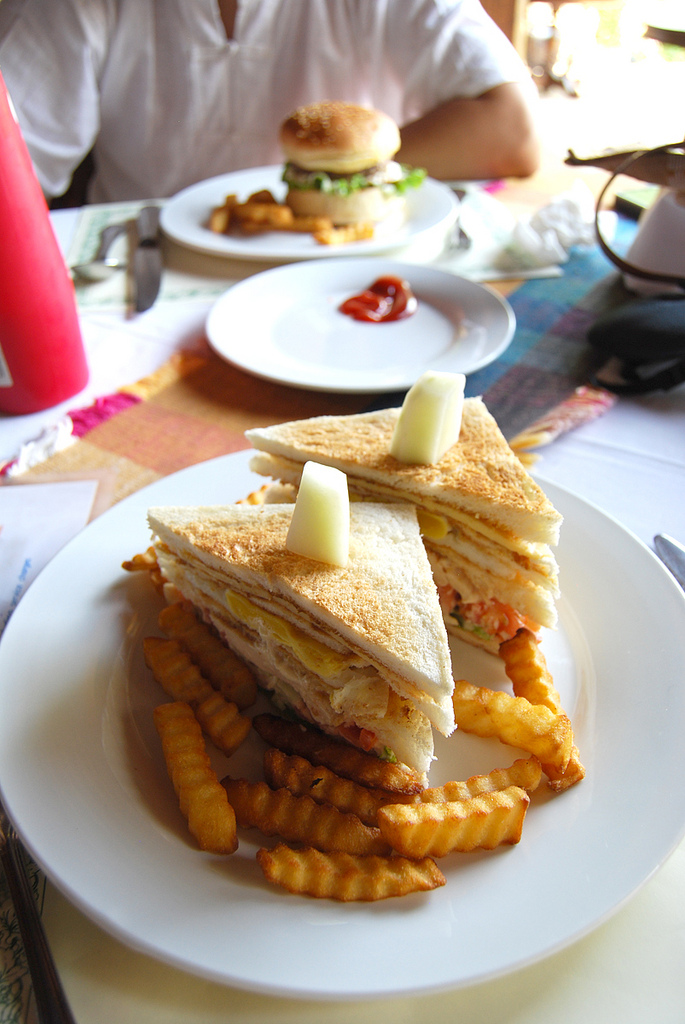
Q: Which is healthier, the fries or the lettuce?
A: The lettuce is healthier than the fries.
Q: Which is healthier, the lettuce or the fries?
A: The lettuce is healthier than the fries.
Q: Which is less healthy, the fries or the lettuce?
A: The fries is less healthy than the lettuce.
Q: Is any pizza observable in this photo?
A: No, there are no pizzas.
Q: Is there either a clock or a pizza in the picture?
A: No, there are no pizzas or clocks.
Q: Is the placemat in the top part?
A: Yes, the placemat is in the top of the image.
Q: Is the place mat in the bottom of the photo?
A: No, the place mat is in the top of the image.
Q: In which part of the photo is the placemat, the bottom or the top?
A: The placemat is in the top of the image.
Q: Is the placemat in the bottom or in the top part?
A: The placemat is in the top of the image.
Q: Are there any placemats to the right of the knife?
A: Yes, there is a placemat to the right of the knife.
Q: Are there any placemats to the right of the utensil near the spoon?
A: Yes, there is a placemat to the right of the knife.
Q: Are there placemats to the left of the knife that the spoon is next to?
A: No, the placemat is to the right of the knife.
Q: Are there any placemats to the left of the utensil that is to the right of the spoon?
A: No, the placemat is to the right of the knife.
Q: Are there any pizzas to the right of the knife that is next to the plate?
A: No, there is a placemat to the right of the knife.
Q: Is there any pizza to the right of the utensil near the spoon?
A: No, there is a placemat to the right of the knife.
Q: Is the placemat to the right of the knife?
A: Yes, the placemat is to the right of the knife.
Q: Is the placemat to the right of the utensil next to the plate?
A: Yes, the placemat is to the right of the knife.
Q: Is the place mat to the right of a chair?
A: No, the place mat is to the right of the knife.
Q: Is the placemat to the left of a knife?
A: No, the placemat is to the right of a knife.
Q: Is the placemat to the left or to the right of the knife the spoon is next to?
A: The placemat is to the right of the knife.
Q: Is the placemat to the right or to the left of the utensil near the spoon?
A: The placemat is to the right of the knife.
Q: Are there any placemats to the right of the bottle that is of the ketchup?
A: Yes, there is a placemat to the right of the bottle.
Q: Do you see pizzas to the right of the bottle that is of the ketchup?
A: No, there is a placemat to the right of the bottle.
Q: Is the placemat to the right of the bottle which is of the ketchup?
A: Yes, the placemat is to the right of the bottle.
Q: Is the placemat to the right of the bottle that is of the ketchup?
A: Yes, the placemat is to the right of the bottle.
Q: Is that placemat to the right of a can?
A: No, the placemat is to the right of the bottle.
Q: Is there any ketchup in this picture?
A: Yes, there is ketchup.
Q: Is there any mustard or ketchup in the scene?
A: Yes, there is ketchup.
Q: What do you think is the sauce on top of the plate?
A: The sauce is ketchup.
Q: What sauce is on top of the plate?
A: The sauce is ketchup.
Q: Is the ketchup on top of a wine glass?
A: No, the ketchup is on top of a plate.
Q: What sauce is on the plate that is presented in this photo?
A: The sauce is ketchup.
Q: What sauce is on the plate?
A: The sauce is ketchup.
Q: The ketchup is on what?
A: The ketchup is on the plate.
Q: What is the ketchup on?
A: The ketchup is on the plate.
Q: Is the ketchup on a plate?
A: Yes, the ketchup is on a plate.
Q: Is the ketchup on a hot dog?
A: No, the ketchup is on a plate.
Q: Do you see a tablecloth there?
A: Yes, there is a tablecloth.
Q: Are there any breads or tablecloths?
A: Yes, there is a tablecloth.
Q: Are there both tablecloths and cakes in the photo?
A: No, there is a tablecloth but no cakes.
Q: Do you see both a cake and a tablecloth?
A: No, there is a tablecloth but no cakes.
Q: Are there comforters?
A: No, there are no comforters.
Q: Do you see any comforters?
A: No, there are no comforters.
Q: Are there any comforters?
A: No, there are no comforters.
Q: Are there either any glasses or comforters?
A: No, there are no comforters or glasses.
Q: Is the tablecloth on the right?
A: Yes, the tablecloth is on the right of the image.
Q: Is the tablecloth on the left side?
A: No, the tablecloth is on the right of the image.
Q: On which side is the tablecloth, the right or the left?
A: The tablecloth is on the right of the image.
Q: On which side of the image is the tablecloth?
A: The tablecloth is on the right of the image.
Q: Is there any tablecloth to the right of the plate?
A: Yes, there is a tablecloth to the right of the plate.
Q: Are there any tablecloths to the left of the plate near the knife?
A: No, the tablecloth is to the right of the plate.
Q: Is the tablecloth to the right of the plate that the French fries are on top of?
A: Yes, the tablecloth is to the right of the plate.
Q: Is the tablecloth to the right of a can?
A: No, the tablecloth is to the right of the plate.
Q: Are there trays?
A: No, there are no trays.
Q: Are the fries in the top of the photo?
A: Yes, the fries are in the top of the image.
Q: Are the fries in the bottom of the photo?
A: No, the fries are in the top of the image.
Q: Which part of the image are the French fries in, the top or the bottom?
A: The French fries are in the top of the image.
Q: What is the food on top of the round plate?
A: The food is fries.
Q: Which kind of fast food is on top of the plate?
A: The food is fries.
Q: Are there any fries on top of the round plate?
A: Yes, there are fries on top of the plate.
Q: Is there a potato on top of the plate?
A: No, there are fries on top of the plate.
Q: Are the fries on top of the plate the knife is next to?
A: Yes, the fries are on top of the plate.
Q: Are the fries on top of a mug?
A: No, the fries are on top of the plate.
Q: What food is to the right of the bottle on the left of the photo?
A: The food is fries.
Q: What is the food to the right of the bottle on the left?
A: The food is fries.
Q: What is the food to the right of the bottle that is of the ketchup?
A: The food is fries.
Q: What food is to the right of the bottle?
A: The food is fries.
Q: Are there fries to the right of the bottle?
A: Yes, there are fries to the right of the bottle.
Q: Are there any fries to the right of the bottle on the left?
A: Yes, there are fries to the right of the bottle.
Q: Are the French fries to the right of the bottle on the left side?
A: Yes, the French fries are to the right of the bottle.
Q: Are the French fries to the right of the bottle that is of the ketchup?
A: Yes, the French fries are to the right of the bottle.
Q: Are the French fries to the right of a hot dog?
A: No, the French fries are to the right of the bottle.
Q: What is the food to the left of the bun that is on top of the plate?
A: The food is fries.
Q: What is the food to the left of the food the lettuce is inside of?
A: The food is fries.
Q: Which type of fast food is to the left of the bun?
A: The food is fries.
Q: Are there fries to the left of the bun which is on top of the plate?
A: Yes, there are fries to the left of the bun.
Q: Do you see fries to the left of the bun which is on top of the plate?
A: Yes, there are fries to the left of the bun.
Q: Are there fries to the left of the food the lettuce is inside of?
A: Yes, there are fries to the left of the bun.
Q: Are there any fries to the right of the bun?
A: No, the fries are to the left of the bun.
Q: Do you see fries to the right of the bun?
A: No, the fries are to the left of the bun.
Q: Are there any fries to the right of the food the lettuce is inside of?
A: No, the fries are to the left of the bun.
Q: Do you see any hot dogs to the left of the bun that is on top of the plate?
A: No, there are fries to the left of the bun.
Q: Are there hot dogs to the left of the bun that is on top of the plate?
A: No, there are fries to the left of the bun.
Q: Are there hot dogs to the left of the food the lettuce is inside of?
A: No, there are fries to the left of the bun.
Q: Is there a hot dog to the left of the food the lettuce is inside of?
A: No, there are fries to the left of the bun.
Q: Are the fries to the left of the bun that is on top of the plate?
A: Yes, the fries are to the left of the bun.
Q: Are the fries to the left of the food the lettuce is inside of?
A: Yes, the fries are to the left of the bun.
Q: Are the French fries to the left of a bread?
A: No, the French fries are to the left of the bun.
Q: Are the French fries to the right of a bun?
A: No, the French fries are to the left of a bun.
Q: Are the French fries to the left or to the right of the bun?
A: The French fries are to the left of the bun.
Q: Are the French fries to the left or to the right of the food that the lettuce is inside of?
A: The French fries are to the left of the bun.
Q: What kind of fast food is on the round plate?
A: The food is fries.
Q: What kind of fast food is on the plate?
A: The food is fries.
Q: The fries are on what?
A: The fries are on the plate.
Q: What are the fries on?
A: The fries are on the plate.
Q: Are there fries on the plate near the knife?
A: Yes, there are fries on the plate.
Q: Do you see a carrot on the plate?
A: No, there are fries on the plate.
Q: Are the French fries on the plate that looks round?
A: Yes, the French fries are on the plate.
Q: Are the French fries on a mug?
A: No, the French fries are on the plate.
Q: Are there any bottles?
A: Yes, there is a bottle.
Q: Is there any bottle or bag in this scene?
A: Yes, there is a bottle.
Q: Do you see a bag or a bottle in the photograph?
A: Yes, there is a bottle.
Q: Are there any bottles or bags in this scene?
A: Yes, there is a bottle.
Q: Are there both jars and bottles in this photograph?
A: No, there is a bottle but no jars.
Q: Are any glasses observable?
A: No, there are no glasses.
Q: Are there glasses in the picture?
A: No, there are no glasses.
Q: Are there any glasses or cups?
A: No, there are no glasses or cups.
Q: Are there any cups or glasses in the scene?
A: No, there are no glasses or cups.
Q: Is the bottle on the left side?
A: Yes, the bottle is on the left of the image.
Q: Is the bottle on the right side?
A: No, the bottle is on the left of the image.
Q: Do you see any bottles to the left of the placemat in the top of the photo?
A: Yes, there is a bottle to the left of the placemat.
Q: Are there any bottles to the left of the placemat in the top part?
A: Yes, there is a bottle to the left of the placemat.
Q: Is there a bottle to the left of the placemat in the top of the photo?
A: Yes, there is a bottle to the left of the placemat.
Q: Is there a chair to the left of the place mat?
A: No, there is a bottle to the left of the place mat.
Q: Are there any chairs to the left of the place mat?
A: No, there is a bottle to the left of the place mat.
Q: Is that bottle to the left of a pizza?
A: No, the bottle is to the left of a placemat.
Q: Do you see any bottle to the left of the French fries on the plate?
A: Yes, there is a bottle to the left of the fries.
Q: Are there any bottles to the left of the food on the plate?
A: Yes, there is a bottle to the left of the fries.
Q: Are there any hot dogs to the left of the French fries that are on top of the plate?
A: No, there is a bottle to the left of the French fries.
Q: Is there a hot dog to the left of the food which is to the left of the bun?
A: No, there is a bottle to the left of the French fries.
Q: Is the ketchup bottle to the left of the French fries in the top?
A: Yes, the bottle is to the left of the French fries.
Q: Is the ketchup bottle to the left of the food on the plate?
A: Yes, the bottle is to the left of the French fries.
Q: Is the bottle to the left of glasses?
A: No, the bottle is to the left of the French fries.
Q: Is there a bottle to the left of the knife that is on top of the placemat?
A: Yes, there is a bottle to the left of the knife.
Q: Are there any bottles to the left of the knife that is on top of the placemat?
A: Yes, there is a bottle to the left of the knife.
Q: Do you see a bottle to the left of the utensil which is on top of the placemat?
A: Yes, there is a bottle to the left of the knife.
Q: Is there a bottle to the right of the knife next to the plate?
A: No, the bottle is to the left of the knife.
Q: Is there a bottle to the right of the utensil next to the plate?
A: No, the bottle is to the left of the knife.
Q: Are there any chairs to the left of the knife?
A: No, there is a bottle to the left of the knife.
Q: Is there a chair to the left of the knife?
A: No, there is a bottle to the left of the knife.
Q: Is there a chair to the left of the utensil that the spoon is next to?
A: No, there is a bottle to the left of the knife.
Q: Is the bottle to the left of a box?
A: No, the bottle is to the left of the knife.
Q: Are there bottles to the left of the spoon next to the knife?
A: Yes, there is a bottle to the left of the spoon.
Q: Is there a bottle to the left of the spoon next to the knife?
A: Yes, there is a bottle to the left of the spoon.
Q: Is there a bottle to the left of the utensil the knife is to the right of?
A: Yes, there is a bottle to the left of the spoon.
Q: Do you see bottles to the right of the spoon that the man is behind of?
A: No, the bottle is to the left of the spoon.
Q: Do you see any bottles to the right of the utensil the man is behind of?
A: No, the bottle is to the left of the spoon.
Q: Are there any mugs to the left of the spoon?
A: No, there is a bottle to the left of the spoon.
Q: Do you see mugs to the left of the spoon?
A: No, there is a bottle to the left of the spoon.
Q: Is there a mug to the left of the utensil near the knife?
A: No, there is a bottle to the left of the spoon.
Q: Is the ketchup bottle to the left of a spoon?
A: Yes, the bottle is to the left of a spoon.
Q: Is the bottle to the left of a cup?
A: No, the bottle is to the left of a spoon.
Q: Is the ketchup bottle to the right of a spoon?
A: No, the bottle is to the left of a spoon.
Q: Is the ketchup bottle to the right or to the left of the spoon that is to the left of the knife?
A: The bottle is to the left of the spoon.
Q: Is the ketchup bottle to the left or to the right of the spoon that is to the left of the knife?
A: The bottle is to the left of the spoon.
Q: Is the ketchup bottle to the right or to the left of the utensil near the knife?
A: The bottle is to the left of the spoon.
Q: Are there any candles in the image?
A: No, there are no candles.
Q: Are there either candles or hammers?
A: No, there are no candles or hammers.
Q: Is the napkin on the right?
A: Yes, the napkin is on the right of the image.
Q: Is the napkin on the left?
A: No, the napkin is on the right of the image.